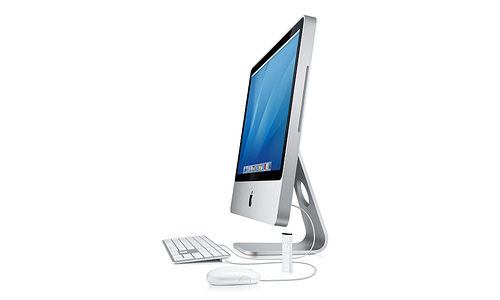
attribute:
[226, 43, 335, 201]
screen — grey, apple, blue, flat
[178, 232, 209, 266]
pad — white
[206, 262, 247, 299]
mouse — white, wired, here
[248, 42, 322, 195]
computer — here, apple, flat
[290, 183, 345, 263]
stand — base, holding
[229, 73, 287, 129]
monitor — on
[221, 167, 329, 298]
parts — grouped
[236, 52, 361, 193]
mac — curved, 3/4, silver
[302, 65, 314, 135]
disk drive — side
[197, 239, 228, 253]
keys — white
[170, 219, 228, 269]
keyboard — elegant, flat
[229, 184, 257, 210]
logo — apple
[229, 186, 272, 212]
symbol — apple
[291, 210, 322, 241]
cord — mouse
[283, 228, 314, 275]
drive — usb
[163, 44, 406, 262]
imac — here